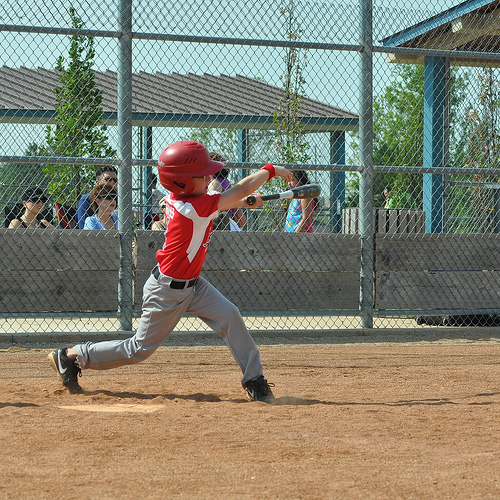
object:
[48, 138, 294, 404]
boy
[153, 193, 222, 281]
shirt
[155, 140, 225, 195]
helmet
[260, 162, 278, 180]
bracelet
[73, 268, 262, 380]
pants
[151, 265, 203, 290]
belt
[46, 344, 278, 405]
shoes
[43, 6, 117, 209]
tree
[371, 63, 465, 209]
tree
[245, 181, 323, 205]
baseball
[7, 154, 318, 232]
people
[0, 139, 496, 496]
game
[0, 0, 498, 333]
fence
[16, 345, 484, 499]
baseball diamond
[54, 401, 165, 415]
home plate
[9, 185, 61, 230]
woman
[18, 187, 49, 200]
visor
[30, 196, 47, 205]
sunglasses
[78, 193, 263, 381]
uniform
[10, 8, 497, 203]
trees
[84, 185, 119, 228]
person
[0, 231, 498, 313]
wooden boards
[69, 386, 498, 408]
shadow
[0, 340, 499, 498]
baseball field